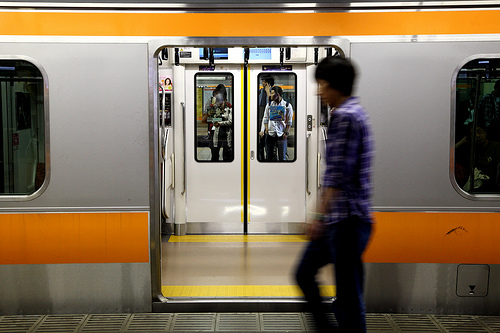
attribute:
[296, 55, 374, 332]
man — blurry, in foreground, side view, blurred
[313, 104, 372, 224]
shirt — plaid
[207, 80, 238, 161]
person — standing, passenger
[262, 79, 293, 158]
person — standing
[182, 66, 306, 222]
door — white, open, closed, yellow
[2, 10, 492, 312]
train — silver, metallic, grey, in foreground, gray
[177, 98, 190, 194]
handle — silver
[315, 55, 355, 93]
hair — dark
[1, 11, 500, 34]
stripe — yellow, orange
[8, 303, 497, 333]
pavement — metal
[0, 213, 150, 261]
stripe — yellow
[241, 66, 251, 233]
stripe — yellow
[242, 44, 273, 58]
ad — blue